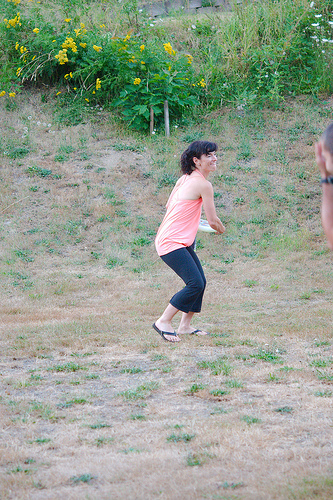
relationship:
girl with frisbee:
[168, 168, 213, 310] [202, 223, 218, 237]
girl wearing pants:
[168, 168, 213, 310] [168, 246, 207, 291]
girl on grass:
[168, 168, 213, 310] [61, 336, 160, 406]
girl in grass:
[168, 168, 213, 310] [61, 336, 160, 406]